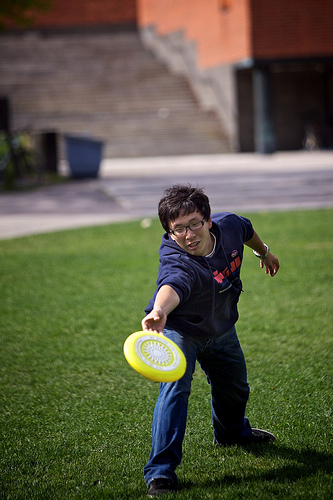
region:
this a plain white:
[88, 48, 332, 103]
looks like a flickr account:
[102, 14, 332, 281]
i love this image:
[121, 89, 275, 320]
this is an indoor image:
[40, 114, 332, 331]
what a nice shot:
[48, 94, 332, 329]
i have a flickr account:
[70, 153, 332, 363]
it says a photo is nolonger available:
[46, 112, 332, 362]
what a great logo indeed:
[62, 124, 332, 266]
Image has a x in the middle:
[175, 131, 321, 221]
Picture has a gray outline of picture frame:
[195, 140, 295, 220]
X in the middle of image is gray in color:
[225, 170, 270, 205]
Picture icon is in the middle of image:
[200, 136, 306, 221]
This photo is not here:
[144, 232, 214, 255]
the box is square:
[216, 167, 283, 212]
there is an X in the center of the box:
[236, 175, 266, 202]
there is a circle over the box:
[242, 147, 257, 163]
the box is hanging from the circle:
[210, 146, 305, 223]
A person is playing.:
[105, 199, 276, 471]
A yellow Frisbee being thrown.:
[121, 320, 185, 389]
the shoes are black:
[144, 472, 172, 496]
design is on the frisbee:
[132, 335, 182, 380]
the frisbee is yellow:
[128, 334, 186, 379]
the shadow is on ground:
[249, 435, 324, 487]